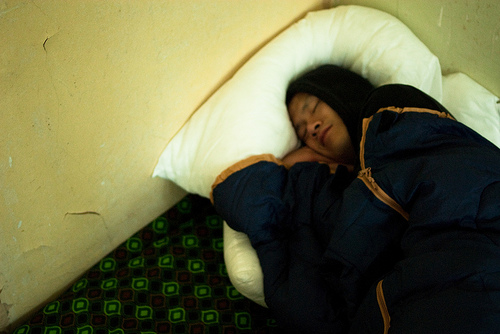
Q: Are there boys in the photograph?
A: No, there are no boys.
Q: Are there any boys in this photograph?
A: No, there are no boys.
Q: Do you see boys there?
A: No, there are no boys.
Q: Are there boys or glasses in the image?
A: No, there are no boys or glasses.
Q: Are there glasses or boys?
A: No, there are no boys or glasses.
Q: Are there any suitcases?
A: No, there are no suitcases.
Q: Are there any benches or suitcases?
A: No, there are no suitcases or benches.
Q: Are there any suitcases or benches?
A: No, there are no suitcases or benches.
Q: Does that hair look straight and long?
A: Yes, the hair is straight and long.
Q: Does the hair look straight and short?
A: No, the hair is straight but long.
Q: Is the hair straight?
A: Yes, the hair is straight.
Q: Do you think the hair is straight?
A: Yes, the hair is straight.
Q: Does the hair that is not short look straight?
A: Yes, the hair is straight.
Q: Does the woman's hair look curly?
A: No, the hair is straight.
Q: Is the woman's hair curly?
A: No, the hair is straight.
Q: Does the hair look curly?
A: No, the hair is straight.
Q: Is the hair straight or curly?
A: The hair is straight.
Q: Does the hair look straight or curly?
A: The hair is straight.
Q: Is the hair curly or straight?
A: The hair is straight.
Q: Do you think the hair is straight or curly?
A: The hair is straight.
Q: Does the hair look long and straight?
A: Yes, the hair is long and straight.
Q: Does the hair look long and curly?
A: No, the hair is long but straight.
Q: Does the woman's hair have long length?
A: Yes, the hair is long.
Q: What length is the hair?
A: The hair is long.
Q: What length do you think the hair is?
A: The hair is long.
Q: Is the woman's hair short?
A: No, the hair is long.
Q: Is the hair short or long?
A: The hair is long.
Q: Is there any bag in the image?
A: Yes, there is a bag.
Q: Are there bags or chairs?
A: Yes, there is a bag.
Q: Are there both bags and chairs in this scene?
A: No, there is a bag but no chairs.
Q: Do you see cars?
A: No, there are no cars.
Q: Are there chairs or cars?
A: No, there are no cars or chairs.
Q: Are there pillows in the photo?
A: Yes, there is a pillow.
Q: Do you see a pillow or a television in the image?
A: Yes, there is a pillow.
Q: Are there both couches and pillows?
A: No, there is a pillow but no couches.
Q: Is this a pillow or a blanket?
A: This is a pillow.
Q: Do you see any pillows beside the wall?
A: Yes, there is a pillow beside the wall.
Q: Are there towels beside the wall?
A: No, there is a pillow beside the wall.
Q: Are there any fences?
A: No, there are no fences.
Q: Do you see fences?
A: No, there are no fences.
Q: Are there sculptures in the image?
A: No, there are no sculptures.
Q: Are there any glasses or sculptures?
A: No, there are no sculptures or glasses.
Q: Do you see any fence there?
A: No, there are no fences.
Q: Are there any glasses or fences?
A: No, there are no fences or glasses.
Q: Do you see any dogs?
A: No, there are no dogs.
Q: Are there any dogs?
A: No, there are no dogs.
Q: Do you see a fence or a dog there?
A: No, there are no dogs or fences.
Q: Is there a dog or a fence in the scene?
A: No, there are no dogs or fences.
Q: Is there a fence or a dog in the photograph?
A: No, there are no dogs or fences.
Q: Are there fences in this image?
A: No, there are no fences.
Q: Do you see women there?
A: Yes, there is a woman.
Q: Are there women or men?
A: Yes, there is a woman.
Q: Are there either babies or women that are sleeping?
A: Yes, the woman is sleeping.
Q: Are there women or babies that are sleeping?
A: Yes, the woman is sleeping.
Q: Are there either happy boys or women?
A: Yes, there is a happy woman.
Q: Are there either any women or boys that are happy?
A: Yes, the woman is happy.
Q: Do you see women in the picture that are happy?
A: Yes, there is a happy woman.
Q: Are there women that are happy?
A: Yes, there is a woman that is happy.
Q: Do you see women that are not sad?
A: Yes, there is a happy woman.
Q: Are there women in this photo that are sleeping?
A: Yes, there is a woman that is sleeping.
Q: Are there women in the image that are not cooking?
A: Yes, there is a woman that is sleeping.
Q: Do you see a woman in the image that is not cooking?
A: Yes, there is a woman that is sleeping .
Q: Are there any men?
A: No, there are no men.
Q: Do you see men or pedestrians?
A: No, there are no men or pedestrians.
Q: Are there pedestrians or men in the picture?
A: No, there are no men or pedestrians.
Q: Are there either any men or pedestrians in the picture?
A: No, there are no men or pedestrians.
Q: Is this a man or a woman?
A: This is a woman.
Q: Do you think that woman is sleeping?
A: Yes, the woman is sleeping.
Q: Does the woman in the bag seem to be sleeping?
A: Yes, the woman is sleeping.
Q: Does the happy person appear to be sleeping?
A: Yes, the woman is sleeping.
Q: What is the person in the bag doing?
A: The woman is sleeping.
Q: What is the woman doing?
A: The woman is sleeping.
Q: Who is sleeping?
A: The woman is sleeping.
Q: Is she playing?
A: No, the woman is sleeping.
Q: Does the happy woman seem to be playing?
A: No, the woman is sleeping.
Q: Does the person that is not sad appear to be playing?
A: No, the woman is sleeping.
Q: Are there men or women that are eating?
A: No, there is a woman but she is sleeping.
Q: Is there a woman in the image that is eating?
A: No, there is a woman but she is sleeping.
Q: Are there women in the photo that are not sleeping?
A: No, there is a woman but she is sleeping.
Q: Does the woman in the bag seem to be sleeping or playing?
A: The woman is sleeping.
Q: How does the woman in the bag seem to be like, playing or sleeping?
A: The woman is sleeping.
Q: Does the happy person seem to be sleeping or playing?
A: The woman is sleeping.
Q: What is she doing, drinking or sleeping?
A: The woman is sleeping.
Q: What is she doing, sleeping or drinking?
A: The woman is sleeping.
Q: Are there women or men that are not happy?
A: No, there is a woman but she is happy.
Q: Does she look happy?
A: Yes, the woman is happy.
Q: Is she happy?
A: Yes, the woman is happy.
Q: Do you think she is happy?
A: Yes, the woman is happy.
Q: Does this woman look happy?
A: Yes, the woman is happy.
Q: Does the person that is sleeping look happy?
A: Yes, the woman is happy.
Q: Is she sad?
A: No, the woman is happy.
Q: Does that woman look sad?
A: No, the woman is happy.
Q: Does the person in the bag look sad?
A: No, the woman is happy.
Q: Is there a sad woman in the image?
A: No, there is a woman but she is happy.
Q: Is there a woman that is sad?
A: No, there is a woman but she is happy.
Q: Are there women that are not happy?
A: No, there is a woman but she is happy.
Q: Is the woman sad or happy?
A: The woman is happy.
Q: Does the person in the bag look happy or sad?
A: The woman is happy.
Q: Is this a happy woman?
A: Yes, this is a happy woman.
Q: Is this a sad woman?
A: No, this is a happy woman.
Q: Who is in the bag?
A: The woman is in the bag.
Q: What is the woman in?
A: The woman is in the bag.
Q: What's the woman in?
A: The woman is in the bag.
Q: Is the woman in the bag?
A: Yes, the woman is in the bag.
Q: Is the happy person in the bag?
A: Yes, the woman is in the bag.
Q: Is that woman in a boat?
A: No, the woman is in the bag.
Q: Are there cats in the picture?
A: No, there are no cats.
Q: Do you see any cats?
A: No, there are no cats.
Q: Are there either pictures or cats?
A: No, there are no cats or pictures.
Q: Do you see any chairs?
A: No, there are no chairs.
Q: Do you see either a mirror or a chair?
A: No, there are no chairs or mirrors.